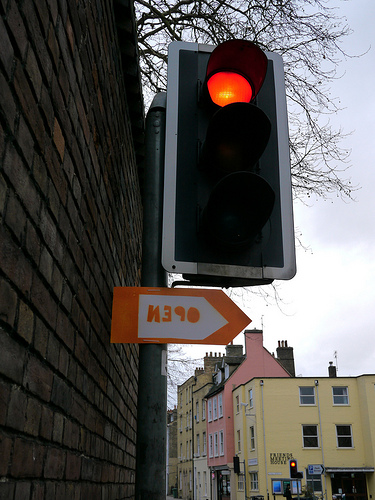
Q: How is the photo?
A: Clear.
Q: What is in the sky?
A: Clouds.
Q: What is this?
A: Traffic pole.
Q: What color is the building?
A: Yellow.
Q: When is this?
A: Daytime.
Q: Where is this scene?
A: A city corner.